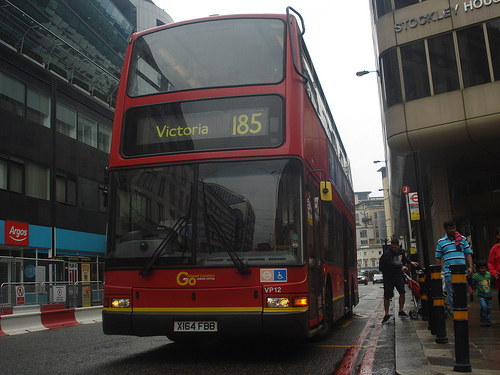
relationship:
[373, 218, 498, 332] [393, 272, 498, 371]
people on sidewalk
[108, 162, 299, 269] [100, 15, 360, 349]
windshield on bus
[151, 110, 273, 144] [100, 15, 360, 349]
sign on bus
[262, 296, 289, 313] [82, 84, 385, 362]
headlight on bus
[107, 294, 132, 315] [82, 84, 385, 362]
headlight on bus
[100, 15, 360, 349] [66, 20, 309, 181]
bus with upper deck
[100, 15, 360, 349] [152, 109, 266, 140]
bus says victoria 185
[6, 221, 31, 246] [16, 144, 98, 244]
company logo on a wall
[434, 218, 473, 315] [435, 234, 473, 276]
man with shirt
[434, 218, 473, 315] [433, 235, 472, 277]
man with blue stripes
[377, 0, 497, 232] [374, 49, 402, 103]
large building with tall window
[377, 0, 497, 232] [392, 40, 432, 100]
large building with tall window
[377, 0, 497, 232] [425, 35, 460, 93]
large building with tall window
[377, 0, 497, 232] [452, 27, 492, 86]
large building with tall window